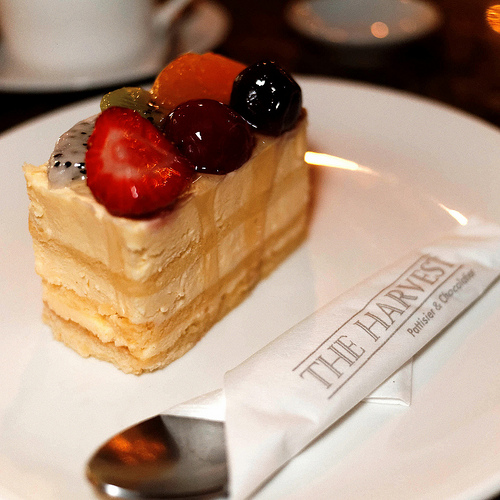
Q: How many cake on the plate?
A: One.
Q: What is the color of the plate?
A: White.